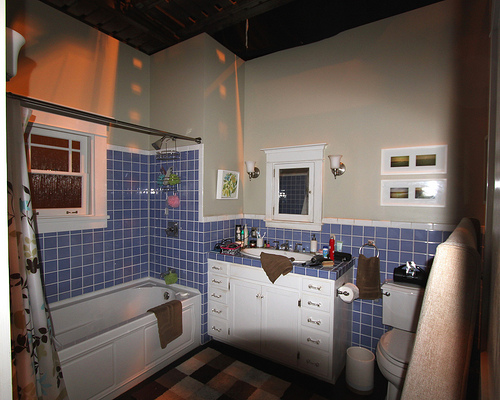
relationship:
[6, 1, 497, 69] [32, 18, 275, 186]
ceiling lets light